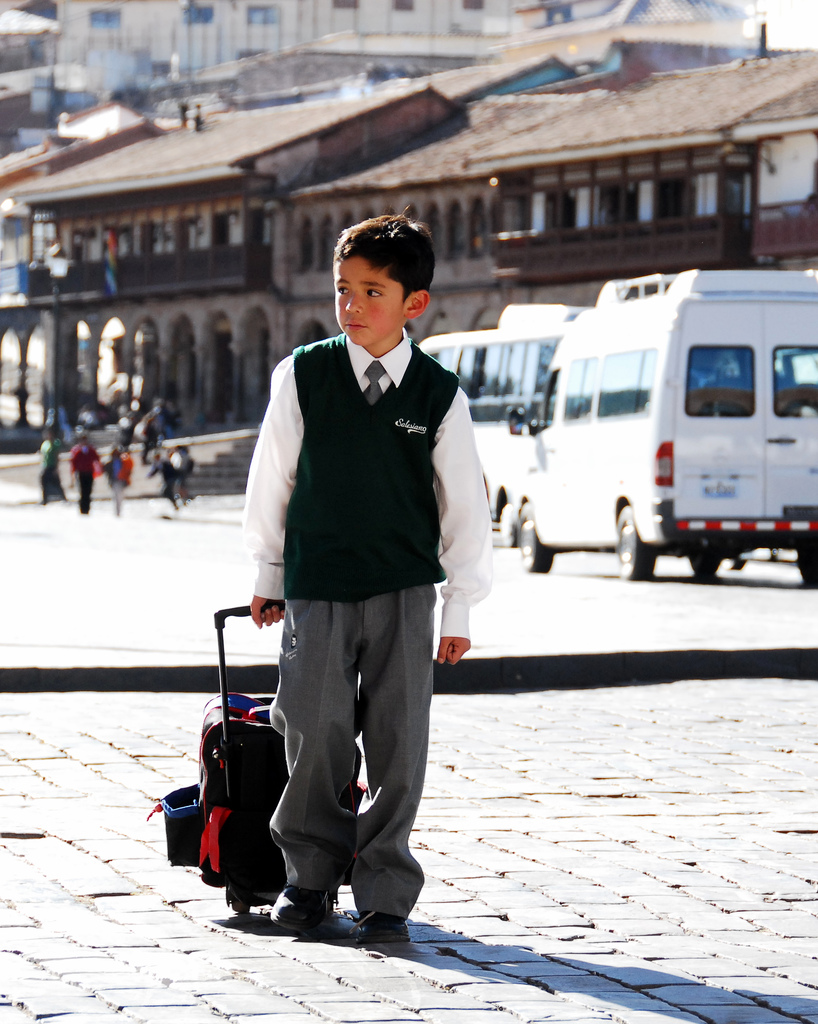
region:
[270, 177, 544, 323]
boy has brown hair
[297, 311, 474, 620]
boy has green vest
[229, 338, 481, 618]
boy has white shirt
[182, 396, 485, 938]
boy has grey slacks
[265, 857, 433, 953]
boy has black shoes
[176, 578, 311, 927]
boy is rolling backpack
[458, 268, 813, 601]
white van is parked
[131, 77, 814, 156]
brown roofs on buildings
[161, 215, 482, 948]
a boy pulling a suitcase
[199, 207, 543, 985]
a boy walking on cobblestones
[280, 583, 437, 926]
a person wearing grey pants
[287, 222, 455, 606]
a boy wearing a green sweater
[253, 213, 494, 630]
a boy wearing a white shirt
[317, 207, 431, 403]
a boy wearing a grey neck tie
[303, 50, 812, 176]
the brown roof of a building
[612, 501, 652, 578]
the wheel of a vehicle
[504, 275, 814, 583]
a white passenger van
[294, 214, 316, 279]
a window on a building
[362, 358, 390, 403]
a boy's grey neck tie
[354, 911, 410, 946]
a boy's left shoe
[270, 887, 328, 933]
a boy's right shoe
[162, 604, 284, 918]
a piece of luggage with wheels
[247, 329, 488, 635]
white dress shirt with sweater vest and grey tie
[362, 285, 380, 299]
a boy's left eye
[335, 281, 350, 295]
a boy's right eye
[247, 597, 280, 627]
a boy's right hand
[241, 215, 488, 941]
boy wearing green vest and gray pants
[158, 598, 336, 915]
black and red wheeled bag with long handle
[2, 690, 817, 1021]
road covered with cobblestones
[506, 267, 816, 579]
small white truck with red and white striped bumper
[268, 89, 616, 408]
large brown house with many windows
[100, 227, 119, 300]
rainbow banner hanging from window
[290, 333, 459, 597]
green vest with white logo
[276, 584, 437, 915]
baggy gray pants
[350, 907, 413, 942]
black shoe with beige shoelace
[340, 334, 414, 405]
gray tie underneath white collar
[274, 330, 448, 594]
Vest on a little boy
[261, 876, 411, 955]
Shoes on a little boy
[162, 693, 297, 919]
Suitcase rolling on sidewalk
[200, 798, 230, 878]
Red thing hanging from bag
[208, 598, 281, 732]
Handle of rolling suitcase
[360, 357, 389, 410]
Gray tie on little boy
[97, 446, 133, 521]
Person walking in background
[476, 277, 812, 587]
White van on the road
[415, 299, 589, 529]
White van on the road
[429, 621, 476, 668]
Hand of little boy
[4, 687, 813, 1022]
The brick road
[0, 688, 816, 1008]
A brown brick road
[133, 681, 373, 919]
A black suitcase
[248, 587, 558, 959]
The gray pants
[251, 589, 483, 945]
A pair of gray pants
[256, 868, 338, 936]
A child's left shoe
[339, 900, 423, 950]
The right shoe on the child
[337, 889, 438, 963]
A child's right shoe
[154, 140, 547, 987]
boy holding a suitcase handle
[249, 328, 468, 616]
a dark green vest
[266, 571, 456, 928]
a pair of gray pants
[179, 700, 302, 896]
a small black suitcase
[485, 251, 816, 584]
van on the side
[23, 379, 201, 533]
people in the background